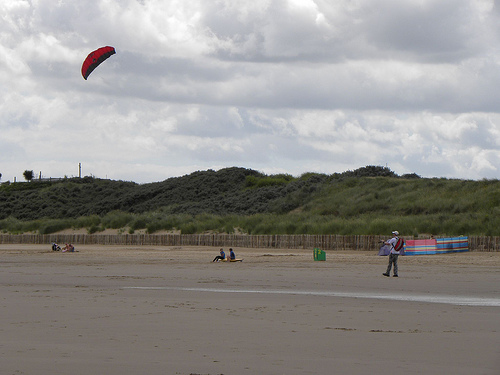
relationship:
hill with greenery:
[0, 162, 484, 244] [0, 211, 484, 231]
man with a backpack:
[379, 230, 404, 278] [393, 233, 406, 252]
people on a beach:
[49, 240, 76, 254] [1, 240, 484, 371]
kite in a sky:
[81, 46, 116, 81] [1, 0, 484, 183]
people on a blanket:
[210, 247, 235, 263] [219, 256, 243, 265]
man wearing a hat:
[379, 230, 404, 278] [390, 230, 399, 235]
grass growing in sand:
[2, 210, 225, 235] [1, 225, 185, 233]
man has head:
[381, 223, 408, 279] [388, 226, 402, 238]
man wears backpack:
[379, 230, 404, 278] [392, 232, 408, 253]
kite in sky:
[79, 39, 117, 82] [1, 0, 484, 183]